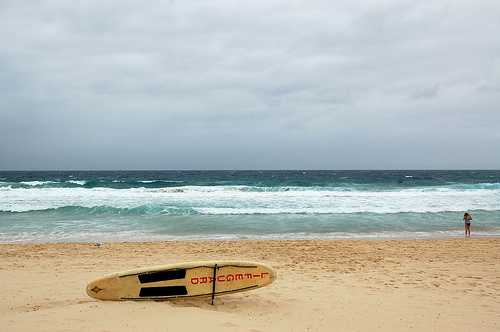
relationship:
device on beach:
[84, 261, 276, 303] [39, 158, 410, 328]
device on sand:
[84, 261, 276, 303] [80, 222, 381, 325]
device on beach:
[84, 261, 276, 303] [16, 185, 275, 326]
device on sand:
[84, 261, 276, 303] [34, 224, 442, 325]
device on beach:
[84, 261, 276, 303] [62, 195, 373, 330]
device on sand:
[84, 261, 276, 303] [49, 203, 419, 303]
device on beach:
[84, 261, 276, 303] [20, 190, 298, 329]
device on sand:
[84, 261, 276, 303] [58, 218, 406, 329]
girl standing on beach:
[462, 212, 472, 235] [0, 232, 498, 331]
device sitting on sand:
[84, 261, 276, 303] [4, 229, 495, 330]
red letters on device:
[189, 267, 276, 287] [82, 261, 279, 302]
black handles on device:
[206, 262, 222, 309] [82, 261, 279, 302]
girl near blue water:
[462, 212, 472, 235] [0, 171, 500, 187]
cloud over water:
[0, 2, 498, 167] [0, 171, 495, 224]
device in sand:
[84, 261, 276, 303] [4, 229, 495, 330]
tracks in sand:
[4, 243, 497, 312] [4, 229, 495, 330]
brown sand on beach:
[0, 239, 500, 332] [0, 226, 500, 332]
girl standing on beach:
[462, 212, 472, 235] [0, 226, 500, 332]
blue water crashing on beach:
[0, 171, 500, 187] [0, 226, 500, 332]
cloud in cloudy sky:
[0, 2, 498, 167] [0, 1, 500, 168]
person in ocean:
[285, 185, 291, 192] [0, 171, 494, 215]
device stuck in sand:
[84, 261, 276, 303] [4, 229, 495, 330]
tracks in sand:
[0, 239, 500, 302] [4, 229, 495, 330]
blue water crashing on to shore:
[0, 171, 500, 187] [2, 232, 497, 330]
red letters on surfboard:
[189, 267, 276, 287] [83, 251, 280, 314]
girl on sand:
[459, 208, 475, 236] [346, 225, 449, 304]